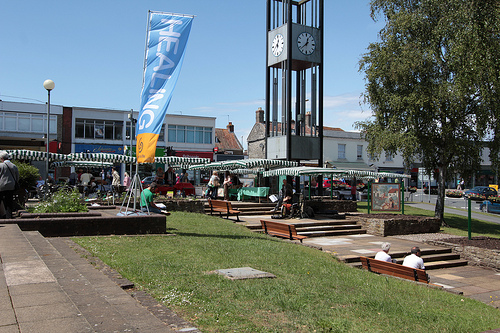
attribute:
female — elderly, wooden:
[374, 242, 395, 263]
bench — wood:
[359, 245, 441, 300]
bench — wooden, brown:
[259, 216, 306, 244]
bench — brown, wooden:
[205, 191, 244, 219]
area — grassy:
[79, 210, 499, 331]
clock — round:
[270, 32, 284, 56]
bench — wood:
[358, 259, 445, 289]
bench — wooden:
[206, 197, 244, 222]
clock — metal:
[295, 27, 319, 65]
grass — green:
[190, 258, 235, 273]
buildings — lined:
[7, 97, 499, 196]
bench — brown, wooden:
[357, 254, 434, 286]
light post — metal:
[43, 77, 54, 177]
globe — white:
[43, 78, 55, 89]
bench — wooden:
[361, 254, 441, 280]